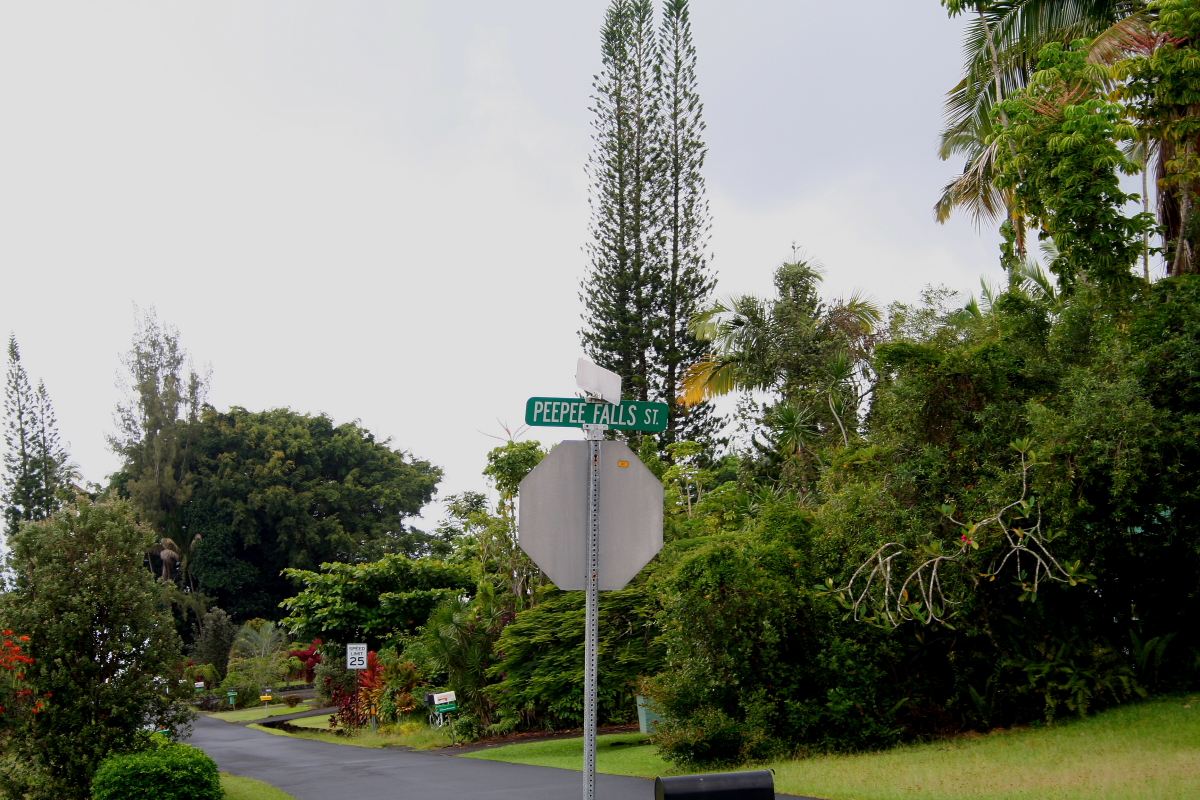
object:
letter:
[552, 402, 559, 422]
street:
[182, 718, 817, 800]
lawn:
[777, 700, 1200, 798]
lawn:
[532, 733, 641, 771]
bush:
[590, 0, 706, 404]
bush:
[0, 338, 58, 626]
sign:
[347, 645, 367, 668]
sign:
[526, 397, 667, 431]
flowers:
[362, 651, 381, 709]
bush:
[501, 592, 653, 723]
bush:
[658, 550, 781, 755]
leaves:
[696, 553, 799, 609]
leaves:
[155, 427, 364, 544]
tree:
[777, 263, 813, 484]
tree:
[132, 292, 199, 578]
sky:
[0, 75, 1176, 419]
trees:
[140, 313, 199, 462]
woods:
[998, 0, 1151, 281]